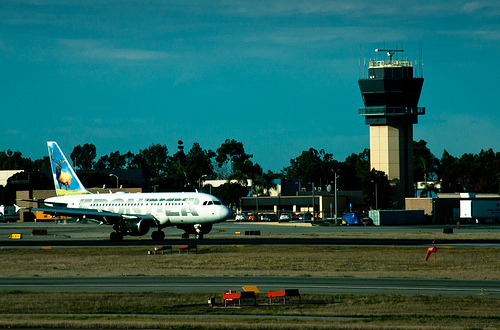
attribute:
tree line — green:
[70, 131, 253, 201]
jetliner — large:
[45, 145, 248, 256]